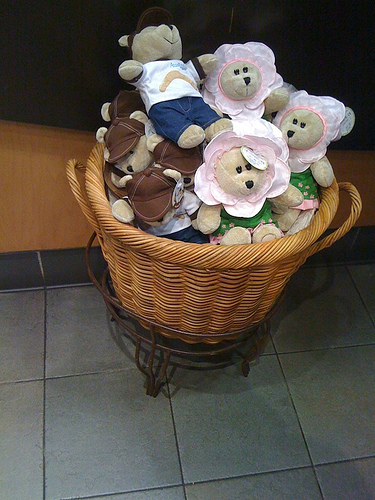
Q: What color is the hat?
A: Brown.